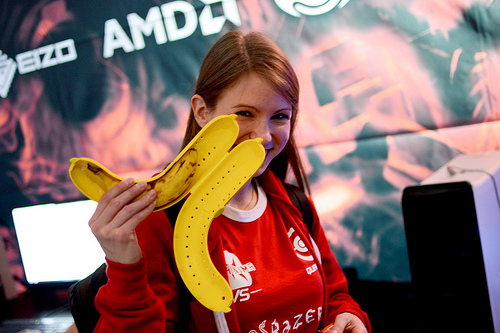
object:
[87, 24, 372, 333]
woman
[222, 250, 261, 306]
logos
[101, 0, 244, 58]
writing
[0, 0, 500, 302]
wall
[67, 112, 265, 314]
banana case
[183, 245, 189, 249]
holes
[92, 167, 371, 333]
jacket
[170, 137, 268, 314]
plastic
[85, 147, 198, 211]
banana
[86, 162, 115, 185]
stem